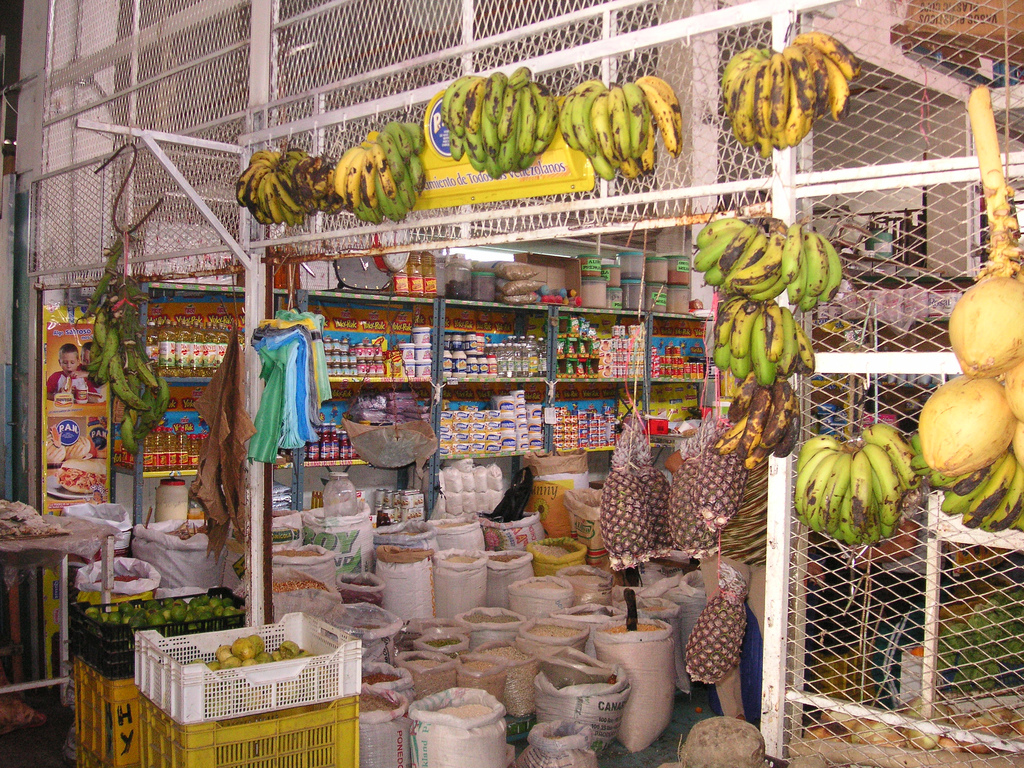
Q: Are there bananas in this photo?
A: Yes, there are bananas.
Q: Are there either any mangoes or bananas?
A: Yes, there are bananas.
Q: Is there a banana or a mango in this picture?
A: Yes, there are bananas.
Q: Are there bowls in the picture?
A: No, there are no bowls.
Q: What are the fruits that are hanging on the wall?
A: The fruits are bananas.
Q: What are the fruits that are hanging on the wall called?
A: The fruits are bananas.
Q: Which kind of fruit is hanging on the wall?
A: The fruits are bananas.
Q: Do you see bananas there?
A: Yes, there are bananas.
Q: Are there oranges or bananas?
A: Yes, there are bananas.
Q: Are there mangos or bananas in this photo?
A: Yes, there are bananas.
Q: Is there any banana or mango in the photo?
A: Yes, there are bananas.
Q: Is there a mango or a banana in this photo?
A: Yes, there are bananas.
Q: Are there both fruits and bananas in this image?
A: Yes, there are both bananas and a fruit.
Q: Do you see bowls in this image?
A: No, there are no bowls.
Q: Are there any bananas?
A: Yes, there are bananas.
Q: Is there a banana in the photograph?
A: Yes, there are bananas.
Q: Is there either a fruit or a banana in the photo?
A: Yes, there are bananas.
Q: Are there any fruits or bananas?
A: Yes, there are bananas.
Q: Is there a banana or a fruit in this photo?
A: Yes, there are bananas.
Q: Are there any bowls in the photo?
A: No, there are no bowls.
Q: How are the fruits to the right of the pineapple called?
A: The fruits are bananas.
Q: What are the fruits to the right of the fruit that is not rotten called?
A: The fruits are bananas.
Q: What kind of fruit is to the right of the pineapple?
A: The fruits are bananas.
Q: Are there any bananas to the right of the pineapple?
A: Yes, there are bananas to the right of the pineapple.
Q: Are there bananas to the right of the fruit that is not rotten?
A: Yes, there are bananas to the right of the pineapple.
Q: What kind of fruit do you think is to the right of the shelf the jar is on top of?
A: The fruits are bananas.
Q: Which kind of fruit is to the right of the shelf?
A: The fruits are bananas.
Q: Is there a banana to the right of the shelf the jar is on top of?
A: Yes, there are bananas to the right of the shelf.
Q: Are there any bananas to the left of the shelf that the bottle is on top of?
A: No, the bananas are to the right of the shelf.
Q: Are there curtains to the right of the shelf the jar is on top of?
A: No, there are bananas to the right of the shelf.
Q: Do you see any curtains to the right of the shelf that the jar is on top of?
A: No, there are bananas to the right of the shelf.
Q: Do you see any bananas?
A: Yes, there are bananas.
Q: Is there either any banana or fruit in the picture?
A: Yes, there are bananas.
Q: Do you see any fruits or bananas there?
A: Yes, there are bananas.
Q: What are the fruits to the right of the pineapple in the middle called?
A: The fruits are bananas.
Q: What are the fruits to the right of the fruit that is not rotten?
A: The fruits are bananas.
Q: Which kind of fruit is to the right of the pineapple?
A: The fruits are bananas.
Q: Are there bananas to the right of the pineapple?
A: Yes, there are bananas to the right of the pineapple.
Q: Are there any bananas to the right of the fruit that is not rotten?
A: Yes, there are bananas to the right of the pineapple.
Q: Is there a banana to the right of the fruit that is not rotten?
A: Yes, there are bananas to the right of the pineapple.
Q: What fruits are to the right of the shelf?
A: The fruits are bananas.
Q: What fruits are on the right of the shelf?
A: The fruits are bananas.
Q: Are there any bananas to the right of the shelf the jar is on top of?
A: Yes, there are bananas to the right of the shelf.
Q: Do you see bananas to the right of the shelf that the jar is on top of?
A: Yes, there are bananas to the right of the shelf.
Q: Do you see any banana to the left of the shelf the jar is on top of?
A: No, the bananas are to the right of the shelf.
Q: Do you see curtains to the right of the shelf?
A: No, there are bananas to the right of the shelf.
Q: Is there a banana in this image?
A: Yes, there are bananas.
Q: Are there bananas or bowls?
A: Yes, there are bananas.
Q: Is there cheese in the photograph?
A: No, there is no cheese.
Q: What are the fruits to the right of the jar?
A: The fruits are bananas.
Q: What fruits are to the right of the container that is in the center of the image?
A: The fruits are bananas.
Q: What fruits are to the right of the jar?
A: The fruits are bananas.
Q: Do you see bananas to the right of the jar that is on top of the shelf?
A: Yes, there are bananas to the right of the jar.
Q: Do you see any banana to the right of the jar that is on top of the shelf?
A: Yes, there are bananas to the right of the jar.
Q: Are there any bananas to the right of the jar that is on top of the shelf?
A: Yes, there are bananas to the right of the jar.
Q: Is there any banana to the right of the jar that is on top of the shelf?
A: Yes, there are bananas to the right of the jar.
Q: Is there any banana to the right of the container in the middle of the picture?
A: Yes, there are bananas to the right of the jar.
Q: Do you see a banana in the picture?
A: Yes, there are bananas.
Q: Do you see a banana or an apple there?
A: Yes, there are bananas.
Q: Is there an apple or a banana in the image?
A: Yes, there are bananas.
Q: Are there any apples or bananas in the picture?
A: Yes, there are bananas.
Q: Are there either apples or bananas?
A: Yes, there is a banana.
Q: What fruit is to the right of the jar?
A: The fruit is a banana.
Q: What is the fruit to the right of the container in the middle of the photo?
A: The fruit is a banana.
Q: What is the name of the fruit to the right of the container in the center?
A: The fruit is a banana.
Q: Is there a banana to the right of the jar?
A: Yes, there is a banana to the right of the jar.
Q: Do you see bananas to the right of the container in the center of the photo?
A: Yes, there is a banana to the right of the jar.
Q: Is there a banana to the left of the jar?
A: No, the banana is to the right of the jar.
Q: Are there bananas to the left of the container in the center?
A: No, the banana is to the right of the jar.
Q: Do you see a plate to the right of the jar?
A: No, there is a banana to the right of the jar.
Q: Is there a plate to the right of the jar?
A: No, there is a banana to the right of the jar.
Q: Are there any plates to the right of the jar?
A: No, there is a banana to the right of the jar.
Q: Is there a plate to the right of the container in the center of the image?
A: No, there is a banana to the right of the jar.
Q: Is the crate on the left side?
A: Yes, the crate is on the left of the image.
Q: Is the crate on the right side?
A: No, the crate is on the left of the image.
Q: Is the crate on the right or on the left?
A: The crate is on the left of the image.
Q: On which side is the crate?
A: The crate is on the left of the image.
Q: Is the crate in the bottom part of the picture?
A: Yes, the crate is in the bottom of the image.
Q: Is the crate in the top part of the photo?
A: No, the crate is in the bottom of the image.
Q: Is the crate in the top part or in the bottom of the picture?
A: The crate is in the bottom of the image.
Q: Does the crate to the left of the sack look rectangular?
A: Yes, the crate is rectangular.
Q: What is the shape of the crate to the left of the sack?
A: The crate is rectangular.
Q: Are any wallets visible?
A: No, there are no wallets.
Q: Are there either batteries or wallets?
A: No, there are no wallets or batteries.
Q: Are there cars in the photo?
A: No, there are no cars.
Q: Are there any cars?
A: No, there are no cars.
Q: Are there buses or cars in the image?
A: No, there are no cars or buses.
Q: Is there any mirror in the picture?
A: No, there are no mirrors.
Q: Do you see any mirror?
A: No, there are no mirrors.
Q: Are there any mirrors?
A: No, there are no mirrors.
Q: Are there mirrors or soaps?
A: No, there are no mirrors or soaps.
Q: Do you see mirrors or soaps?
A: No, there are no mirrors or soaps.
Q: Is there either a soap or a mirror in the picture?
A: No, there are no mirrors or soaps.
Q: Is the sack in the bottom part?
A: Yes, the sack is in the bottom of the image.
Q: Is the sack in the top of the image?
A: No, the sack is in the bottom of the image.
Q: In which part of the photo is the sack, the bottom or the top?
A: The sack is in the bottom of the image.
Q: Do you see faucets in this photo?
A: No, there are no faucets.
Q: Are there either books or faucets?
A: No, there are no faucets or books.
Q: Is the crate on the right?
A: No, the crate is on the left of the image.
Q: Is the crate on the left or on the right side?
A: The crate is on the left of the image.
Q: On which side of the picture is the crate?
A: The crate is on the left of the image.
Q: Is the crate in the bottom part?
A: Yes, the crate is in the bottom of the image.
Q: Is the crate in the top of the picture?
A: No, the crate is in the bottom of the image.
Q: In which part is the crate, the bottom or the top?
A: The crate is in the bottom of the image.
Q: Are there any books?
A: No, there are no books.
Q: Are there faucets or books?
A: No, there are no books or faucets.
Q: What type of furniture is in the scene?
A: The furniture is a shelf.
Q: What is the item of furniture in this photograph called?
A: The piece of furniture is a shelf.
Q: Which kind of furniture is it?
A: The piece of furniture is a shelf.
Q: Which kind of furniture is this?
A: This is a shelf.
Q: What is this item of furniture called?
A: This is a shelf.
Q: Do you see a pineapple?
A: Yes, there is a pineapple.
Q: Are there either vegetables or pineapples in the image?
A: Yes, there is a pineapple.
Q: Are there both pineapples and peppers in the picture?
A: No, there is a pineapple but no peppers.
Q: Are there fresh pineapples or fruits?
A: Yes, there is a fresh pineapple.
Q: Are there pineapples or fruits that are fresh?
A: Yes, the pineapple is fresh.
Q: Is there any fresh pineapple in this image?
A: Yes, there is a fresh pineapple.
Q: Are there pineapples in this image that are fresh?
A: Yes, there is a pineapple that is fresh.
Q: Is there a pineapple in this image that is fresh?
A: Yes, there is a pineapple that is fresh.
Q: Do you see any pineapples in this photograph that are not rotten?
A: Yes, there is a fresh pineapple.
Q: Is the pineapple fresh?
A: Yes, the pineapple is fresh.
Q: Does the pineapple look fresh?
A: Yes, the pineapple is fresh.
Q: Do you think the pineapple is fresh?
A: Yes, the pineapple is fresh.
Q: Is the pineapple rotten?
A: No, the pineapple is fresh.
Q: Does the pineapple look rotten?
A: No, the pineapple is fresh.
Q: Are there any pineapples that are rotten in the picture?
A: No, there is a pineapple but it is fresh.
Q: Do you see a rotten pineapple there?
A: No, there is a pineapple but it is fresh.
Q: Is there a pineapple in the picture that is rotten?
A: No, there is a pineapple but it is fresh.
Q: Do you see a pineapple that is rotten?
A: No, there is a pineapple but it is fresh.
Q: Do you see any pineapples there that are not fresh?
A: No, there is a pineapple but it is fresh.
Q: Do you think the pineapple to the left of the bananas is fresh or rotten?
A: The pineapple is fresh.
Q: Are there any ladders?
A: No, there are no ladders.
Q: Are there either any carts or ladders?
A: No, there are no ladders or carts.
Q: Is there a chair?
A: No, there are no chairs.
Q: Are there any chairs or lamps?
A: No, there are no chairs or lamps.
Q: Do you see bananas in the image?
A: Yes, there is a banana.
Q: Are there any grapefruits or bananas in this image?
A: Yes, there is a banana.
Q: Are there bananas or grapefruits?
A: Yes, there is a banana.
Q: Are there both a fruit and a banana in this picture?
A: Yes, there are both a banana and a fruit.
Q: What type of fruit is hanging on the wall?
A: The fruit is a banana.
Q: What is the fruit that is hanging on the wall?
A: The fruit is a banana.